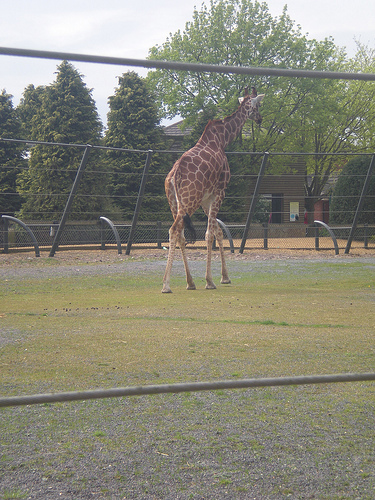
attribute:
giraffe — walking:
[140, 104, 288, 276]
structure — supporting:
[16, 210, 361, 251]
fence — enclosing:
[32, 133, 358, 263]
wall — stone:
[310, 208, 355, 239]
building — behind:
[206, 151, 351, 233]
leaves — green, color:
[48, 86, 79, 135]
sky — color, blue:
[68, 11, 132, 38]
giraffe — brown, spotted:
[162, 98, 274, 226]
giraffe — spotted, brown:
[156, 98, 291, 233]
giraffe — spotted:
[154, 94, 274, 235]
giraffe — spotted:
[162, 92, 264, 194]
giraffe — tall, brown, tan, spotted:
[128, 94, 315, 291]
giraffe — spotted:
[162, 92, 278, 291]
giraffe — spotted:
[160, 90, 299, 303]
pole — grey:
[42, 37, 332, 89]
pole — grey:
[89, 210, 134, 249]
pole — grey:
[7, 208, 60, 272]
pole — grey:
[64, 137, 128, 231]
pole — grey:
[240, 154, 276, 239]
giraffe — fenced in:
[154, 96, 277, 299]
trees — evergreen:
[40, 67, 143, 243]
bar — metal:
[89, 42, 315, 79]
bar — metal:
[61, 357, 315, 418]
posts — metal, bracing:
[36, 128, 202, 284]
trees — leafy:
[28, 70, 156, 214]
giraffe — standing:
[152, 86, 284, 308]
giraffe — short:
[163, 86, 260, 291]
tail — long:
[172, 164, 196, 244]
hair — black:
[184, 214, 194, 244]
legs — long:
[167, 208, 229, 295]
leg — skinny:
[205, 205, 216, 293]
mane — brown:
[198, 98, 247, 135]